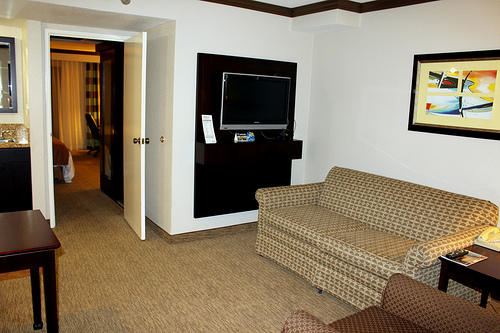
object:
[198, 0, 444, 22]
ceiling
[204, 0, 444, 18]
trim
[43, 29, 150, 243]
door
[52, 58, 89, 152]
curtains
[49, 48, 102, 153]
window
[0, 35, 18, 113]
mirror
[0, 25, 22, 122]
wall